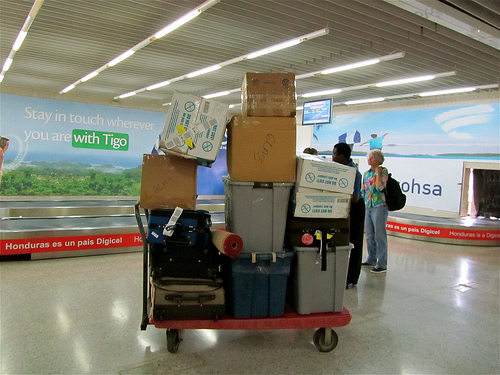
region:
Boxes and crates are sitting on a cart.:
[130, 67, 363, 359]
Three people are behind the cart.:
[295, 139, 412, 277]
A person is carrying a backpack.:
[358, 146, 410, 276]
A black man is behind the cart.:
[318, 133, 368, 293]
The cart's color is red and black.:
[127, 198, 360, 355]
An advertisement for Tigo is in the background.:
[0, 96, 167, 201]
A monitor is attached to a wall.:
[297, 91, 337, 133]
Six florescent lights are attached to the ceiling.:
[0, 0, 499, 131]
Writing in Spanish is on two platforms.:
[0, 216, 498, 256]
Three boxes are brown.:
[135, 64, 302, 213]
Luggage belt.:
[0, 196, 498, 263]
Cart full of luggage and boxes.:
[132, 70, 352, 352]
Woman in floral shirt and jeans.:
[362, 148, 407, 273]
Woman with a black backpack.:
[362, 148, 406, 276]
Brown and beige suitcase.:
[147, 274, 226, 324]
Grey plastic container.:
[293, 240, 352, 315]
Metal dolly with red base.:
[135, 196, 352, 351]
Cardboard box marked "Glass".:
[142, 151, 197, 208]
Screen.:
[302, 96, 331, 125]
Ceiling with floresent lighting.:
[0, 31, 499, 116]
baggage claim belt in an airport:
[409, 155, 496, 257]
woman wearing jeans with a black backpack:
[361, 149, 406, 280]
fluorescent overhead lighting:
[66, 9, 223, 96]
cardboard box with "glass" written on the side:
[228, 114, 298, 180]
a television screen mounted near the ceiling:
[301, 97, 334, 125]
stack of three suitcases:
[143, 207, 228, 323]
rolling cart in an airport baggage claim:
[132, 60, 359, 357]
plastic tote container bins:
[225, 177, 350, 316]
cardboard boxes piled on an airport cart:
[143, 67, 354, 218]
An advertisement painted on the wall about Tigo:
[18, 105, 156, 150]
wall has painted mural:
[0, 91, 229, 204]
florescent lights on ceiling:
[1, 1, 498, 121]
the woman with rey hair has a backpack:
[360, 149, 407, 275]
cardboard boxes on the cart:
[136, 68, 354, 354]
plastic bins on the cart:
[138, 71, 355, 356]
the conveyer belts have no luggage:
[3, 192, 228, 243]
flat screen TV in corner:
[301, 99, 334, 125]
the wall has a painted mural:
[311, 106, 499, 215]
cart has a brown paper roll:
[211, 229, 244, 260]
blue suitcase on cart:
[144, 205, 208, 257]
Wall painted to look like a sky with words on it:
[0, 93, 232, 198]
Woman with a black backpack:
[361, 151, 406, 276]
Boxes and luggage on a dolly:
[132, 71, 352, 355]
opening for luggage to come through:
[459, 160, 498, 220]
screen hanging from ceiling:
[300, 98, 332, 125]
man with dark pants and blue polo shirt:
[330, 142, 366, 289]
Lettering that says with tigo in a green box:
[71, 128, 130, 151]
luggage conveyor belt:
[1, 195, 495, 260]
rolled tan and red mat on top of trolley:
[206, 226, 243, 258]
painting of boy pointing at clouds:
[357, 131, 387, 151]